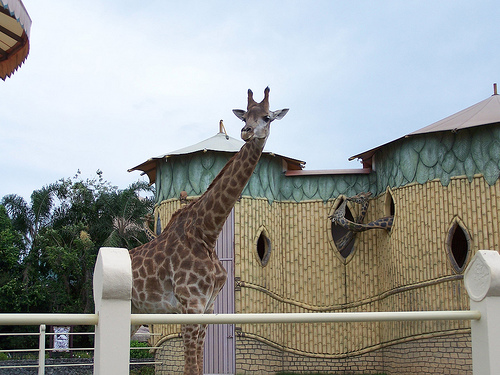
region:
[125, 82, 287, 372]
A giraffe looking at a particular item.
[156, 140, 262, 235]
The thick neck of a large giraffe.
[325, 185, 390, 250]
Two young giraffes interlocking their necks.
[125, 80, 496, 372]
A beautiful house that has animals in it.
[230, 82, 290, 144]
The sad of a large giraffe.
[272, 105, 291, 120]
The ear of a wild giraffe.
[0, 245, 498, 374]
The fence keeping the giraffe from escaping.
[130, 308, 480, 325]
A metallic rod holding a fence.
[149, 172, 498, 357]
A beautiful yellow structure in the house.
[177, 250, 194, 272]
One of the brown spots in giraffe's body.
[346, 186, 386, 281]
Giraffe head sticking out of window.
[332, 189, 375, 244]
Giraffe head sticking out of window.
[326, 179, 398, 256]
Giraffes heads sticking out of windows kissing.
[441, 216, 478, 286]
Diamond shape window on building.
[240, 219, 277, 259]
Diamond shaped window on building.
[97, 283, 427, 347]
White railing in front of giraffe.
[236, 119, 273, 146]
Giraffe has black nose holes.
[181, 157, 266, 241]
Giraffe has long neck.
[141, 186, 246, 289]
Giraffe is brown and tan.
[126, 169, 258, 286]
Giraffe is standing near building.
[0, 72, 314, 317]
giraffe in picture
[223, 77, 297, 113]
horns on top of giraffe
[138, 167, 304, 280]
brown spots on giraffe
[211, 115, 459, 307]
building behind giraffe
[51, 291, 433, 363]
white pole for fence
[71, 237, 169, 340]
wooden post for fence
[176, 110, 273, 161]
roof on top of building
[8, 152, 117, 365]
trees behind giraffe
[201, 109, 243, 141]
pointy tip of building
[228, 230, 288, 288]
hole or window in building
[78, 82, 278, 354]
A giraffe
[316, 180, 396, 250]
a pair of giraffes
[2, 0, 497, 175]
a clear, blue sky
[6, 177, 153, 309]
a group of palm trees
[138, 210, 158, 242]
a giraffe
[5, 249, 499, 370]
a metal fence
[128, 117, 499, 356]
A house for the giraffes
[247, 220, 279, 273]
A window in the giraffe house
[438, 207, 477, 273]
A window in the giraffe house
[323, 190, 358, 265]
A window in the giraffe house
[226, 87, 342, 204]
the giraffe has ears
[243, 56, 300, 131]
the giraffe has ears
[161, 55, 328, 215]
the giraffe has ears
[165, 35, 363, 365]
the giraffe has ears